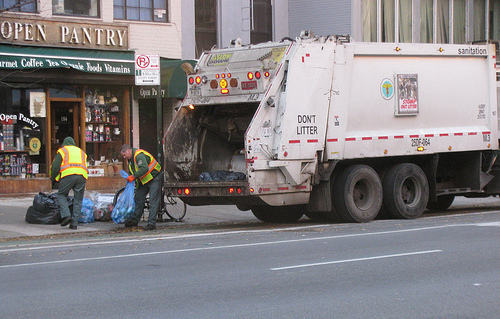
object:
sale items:
[0, 151, 28, 176]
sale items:
[85, 123, 122, 144]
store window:
[47, 82, 82, 99]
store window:
[0, 83, 46, 178]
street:
[0, 207, 500, 319]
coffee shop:
[0, 13, 136, 198]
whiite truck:
[162, 28, 499, 224]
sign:
[133, 53, 161, 86]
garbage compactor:
[161, 46, 287, 196]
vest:
[125, 148, 162, 183]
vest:
[52, 144, 91, 183]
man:
[119, 144, 164, 229]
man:
[48, 136, 88, 231]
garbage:
[26, 192, 74, 225]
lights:
[246, 72, 254, 80]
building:
[0, 0, 182, 200]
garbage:
[200, 170, 233, 182]